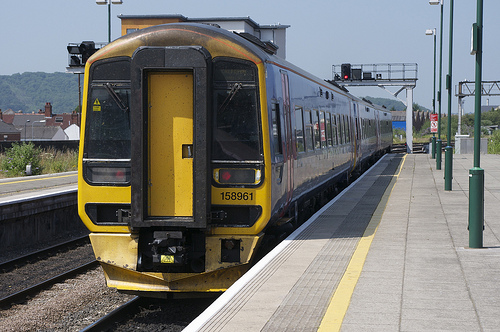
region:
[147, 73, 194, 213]
The yellow door of the train.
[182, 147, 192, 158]
The door handle of the train.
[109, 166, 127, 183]
The left brake light.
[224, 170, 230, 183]
The right brake light.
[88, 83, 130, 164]
The left window.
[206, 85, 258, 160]
The right window.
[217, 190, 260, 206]
The number 158961.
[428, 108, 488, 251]
The green short poles on the platform.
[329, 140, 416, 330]
The yellow line on the platform on the right.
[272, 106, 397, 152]
The side windows of the train.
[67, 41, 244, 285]
yellowo front of train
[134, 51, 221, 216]
yellow door on train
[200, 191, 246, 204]
black number on train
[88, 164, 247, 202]
red lights on train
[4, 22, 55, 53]
blue and hazy sky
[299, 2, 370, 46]
no clouds in sky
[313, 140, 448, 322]
yellow line on platform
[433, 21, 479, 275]
green poles on platform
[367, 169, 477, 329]
platform is light grey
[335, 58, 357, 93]
red light over train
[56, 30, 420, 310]
A train pulling into the platform.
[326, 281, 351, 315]
A yellow dividing stripe.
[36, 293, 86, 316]
Gravel in the train tracks.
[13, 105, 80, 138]
Several building to the left of the train.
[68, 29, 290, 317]
The front of the train is yellow.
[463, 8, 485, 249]
A large green pole.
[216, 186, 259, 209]
Numbers on the front of the train 158961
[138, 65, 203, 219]
A door on the front of the train.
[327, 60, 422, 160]
A train archway through which it passes.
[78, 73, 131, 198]
A large train window.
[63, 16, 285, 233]
this is a train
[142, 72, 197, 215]
this is a door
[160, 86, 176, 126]
the door is yellow in color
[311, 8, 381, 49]
this is the sky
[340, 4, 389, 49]
the sky is blue in color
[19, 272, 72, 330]
this is a railway line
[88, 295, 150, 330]
this is a metal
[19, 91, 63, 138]
this is a building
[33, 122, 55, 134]
this is the roof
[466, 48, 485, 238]
this is a pole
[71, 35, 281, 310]
Train approaching the station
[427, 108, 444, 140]
Sign on the platform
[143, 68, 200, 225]
Door on the train car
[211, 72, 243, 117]
windshield wiper on the window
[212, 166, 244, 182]
light on the train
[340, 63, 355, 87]
red light above the train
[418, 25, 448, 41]
light on a pole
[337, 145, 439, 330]
caution strip on the platform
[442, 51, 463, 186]
green pole on the platform